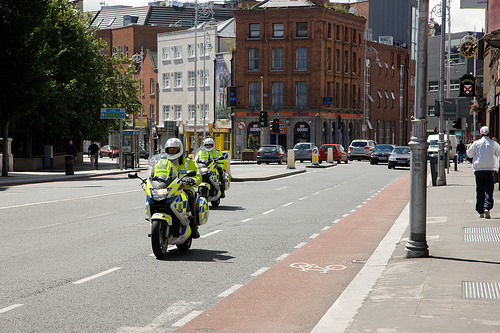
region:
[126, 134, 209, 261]
A man dressed in yellow on a yellow motorcycle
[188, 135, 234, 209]
A man dressed in yellow on a yellow motorcycle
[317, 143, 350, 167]
A small red car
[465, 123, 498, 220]
A man in white walking along the street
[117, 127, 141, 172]
A telephone booth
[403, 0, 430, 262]
A street lamp post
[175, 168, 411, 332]
A biking lane along the street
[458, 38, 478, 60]
A clock along the side of a building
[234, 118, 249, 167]
A no left turn sign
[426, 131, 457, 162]
a white van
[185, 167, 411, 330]
Red Bicycle lane with next to a city street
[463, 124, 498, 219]
Back of person wearing a white jacket and white cap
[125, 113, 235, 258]
Two bikers with matching yellow, blue and black motorcylces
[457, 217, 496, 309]
Gray grates on a gray sidewalk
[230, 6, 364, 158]
Store with apartments above it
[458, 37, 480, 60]
Clock with a black face and orange hands and numbers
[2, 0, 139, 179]
Large tree with green leaves behind a stone wall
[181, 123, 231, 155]
Yellow storefront with a white and red sign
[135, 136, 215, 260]
A biker with a white helmet and black boots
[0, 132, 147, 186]
Man with a dark shirt walking up the street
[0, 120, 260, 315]
two motorcycles on the road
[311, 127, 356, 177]
red vehicle driving down the road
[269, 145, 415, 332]
bicycle lane markings on the road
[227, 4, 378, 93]
brick building with windows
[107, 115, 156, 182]
telephone booth on street corner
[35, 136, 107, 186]
trash can on sidewalk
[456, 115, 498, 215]
person wearing white shirt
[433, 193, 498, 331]
grates in the sidewalk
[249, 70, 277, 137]
green traffic light on pole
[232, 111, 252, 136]
red, black, and white traffic sign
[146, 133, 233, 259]
two people riding motorcycles on street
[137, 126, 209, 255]
person riding neon motorcycle down street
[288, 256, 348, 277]
white symbol of bike lane on street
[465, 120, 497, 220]
person walking down street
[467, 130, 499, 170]
white jacket on person walking down street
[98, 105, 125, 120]
blue sign on street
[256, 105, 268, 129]
traffic light on street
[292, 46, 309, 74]
window on side of building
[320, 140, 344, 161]
red car on street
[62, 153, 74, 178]
black trash can on street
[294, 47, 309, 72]
a window in a building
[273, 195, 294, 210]
a white painted line on a street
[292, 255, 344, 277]
bicycle lane indicator on the road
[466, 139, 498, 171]
a person wearing a white shirt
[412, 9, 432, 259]
a metal pole on a sidewalk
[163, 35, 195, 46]
the white facade of a building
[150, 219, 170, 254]
the front wheel of a motorcycle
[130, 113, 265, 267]
motorcycles driving down the street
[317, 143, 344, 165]
a red colored car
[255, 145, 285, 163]
a grey colored car